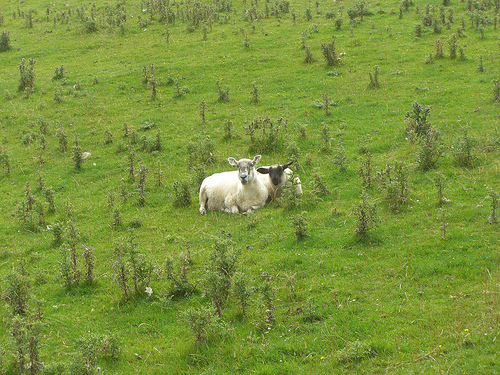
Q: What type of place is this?
A: It is a field.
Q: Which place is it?
A: It is a field.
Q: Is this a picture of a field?
A: Yes, it is showing a field.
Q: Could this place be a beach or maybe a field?
A: It is a field.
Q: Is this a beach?
A: No, it is a field.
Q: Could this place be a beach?
A: No, it is a field.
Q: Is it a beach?
A: No, it is a field.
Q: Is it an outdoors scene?
A: Yes, it is outdoors.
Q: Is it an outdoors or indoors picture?
A: It is outdoors.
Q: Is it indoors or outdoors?
A: It is outdoors.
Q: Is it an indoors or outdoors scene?
A: It is outdoors.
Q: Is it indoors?
A: No, it is outdoors.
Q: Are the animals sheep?
A: Yes, all the animals are sheep.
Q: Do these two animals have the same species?
A: Yes, all the animals are sheep.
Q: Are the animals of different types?
A: No, all the animals are sheep.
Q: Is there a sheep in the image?
A: Yes, there is a sheep.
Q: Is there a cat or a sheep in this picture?
A: Yes, there is a sheep.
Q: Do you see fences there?
A: No, there are no fences.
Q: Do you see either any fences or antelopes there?
A: No, there are no fences or antelopes.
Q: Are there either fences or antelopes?
A: No, there are no fences or antelopes.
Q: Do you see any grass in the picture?
A: Yes, there is grass.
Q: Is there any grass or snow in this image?
A: Yes, there is grass.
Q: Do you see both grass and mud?
A: No, there is grass but no mud.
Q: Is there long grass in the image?
A: Yes, there is long grass.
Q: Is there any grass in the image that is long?
A: Yes, there is grass that is long.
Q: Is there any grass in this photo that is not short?
A: Yes, there is long grass.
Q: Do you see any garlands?
A: No, there are no garlands.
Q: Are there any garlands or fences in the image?
A: No, there are no garlands or fences.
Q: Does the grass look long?
A: Yes, the grass is long.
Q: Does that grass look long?
A: Yes, the grass is long.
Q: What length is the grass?
A: The grass is long.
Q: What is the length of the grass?
A: The grass is long.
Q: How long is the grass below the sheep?
A: The grass is long.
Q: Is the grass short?
A: No, the grass is long.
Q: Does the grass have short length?
A: No, the grass is long.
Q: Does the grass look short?
A: No, the grass is long.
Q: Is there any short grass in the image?
A: No, there is grass but it is long.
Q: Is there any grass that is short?
A: No, there is grass but it is long.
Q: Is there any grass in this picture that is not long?
A: No, there is grass but it is long.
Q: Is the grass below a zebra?
A: No, the grass is below the sheep.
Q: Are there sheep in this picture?
A: Yes, there is a sheep.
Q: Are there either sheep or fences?
A: Yes, there is a sheep.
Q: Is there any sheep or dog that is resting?
A: Yes, the sheep is resting.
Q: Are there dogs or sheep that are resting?
A: Yes, the sheep is resting.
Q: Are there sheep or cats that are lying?
A: Yes, the sheep is lying.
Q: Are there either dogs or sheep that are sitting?
A: Yes, the sheep is sitting.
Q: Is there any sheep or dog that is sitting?
A: Yes, the sheep is sitting.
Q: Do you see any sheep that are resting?
A: Yes, there is a sheep that is resting.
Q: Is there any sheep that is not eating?
A: Yes, there is a sheep that is resting.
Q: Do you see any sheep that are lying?
A: Yes, there is a sheep that is lying.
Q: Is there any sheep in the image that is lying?
A: Yes, there is a sheep that is lying.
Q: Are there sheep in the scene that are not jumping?
A: Yes, there is a sheep that is lying.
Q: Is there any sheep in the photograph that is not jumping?
A: Yes, there is a sheep that is lying.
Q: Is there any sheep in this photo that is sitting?
A: Yes, there is a sheep that is sitting.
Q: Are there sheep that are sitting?
A: Yes, there is a sheep that is sitting.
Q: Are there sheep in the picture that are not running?
A: Yes, there is a sheep that is sitting.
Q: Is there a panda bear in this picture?
A: No, there are no panda bears.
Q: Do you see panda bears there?
A: No, there are no panda bears.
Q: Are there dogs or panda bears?
A: No, there are no panda bears or dogs.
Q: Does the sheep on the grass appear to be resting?
A: Yes, the sheep is resting.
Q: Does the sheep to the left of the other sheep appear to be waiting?
A: No, the sheep is resting.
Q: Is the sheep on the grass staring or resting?
A: The sheep is resting.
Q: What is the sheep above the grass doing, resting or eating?
A: The sheep is resting.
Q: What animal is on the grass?
A: The animal is a sheep.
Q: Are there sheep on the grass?
A: Yes, there is a sheep on the grass.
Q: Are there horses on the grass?
A: No, there is a sheep on the grass.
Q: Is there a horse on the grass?
A: No, there is a sheep on the grass.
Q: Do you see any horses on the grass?
A: No, there is a sheep on the grass.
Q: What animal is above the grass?
A: The animal is a sheep.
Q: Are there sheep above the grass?
A: Yes, there is a sheep above the grass.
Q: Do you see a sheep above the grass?
A: Yes, there is a sheep above the grass.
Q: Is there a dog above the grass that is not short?
A: No, there is a sheep above the grass.